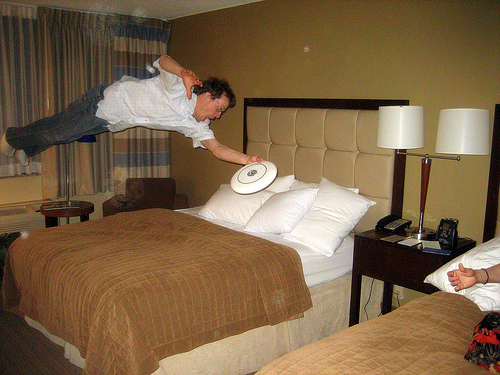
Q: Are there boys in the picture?
A: No, there are no boys.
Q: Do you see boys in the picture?
A: No, there are no boys.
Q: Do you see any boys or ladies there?
A: No, there are no boys or ladies.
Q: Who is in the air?
A: The man is in the air.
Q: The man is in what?
A: The man is in the air.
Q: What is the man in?
A: The man is in the air.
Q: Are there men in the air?
A: Yes, there is a man in the air.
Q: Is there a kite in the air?
A: No, there is a man in the air.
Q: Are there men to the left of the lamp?
A: Yes, there is a man to the left of the lamp.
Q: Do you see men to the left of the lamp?
A: Yes, there is a man to the left of the lamp.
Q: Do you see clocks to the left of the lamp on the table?
A: No, there is a man to the left of the lamp.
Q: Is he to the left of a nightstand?
A: No, the man is to the left of the lamp.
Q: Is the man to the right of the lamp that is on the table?
A: No, the man is to the left of the lamp.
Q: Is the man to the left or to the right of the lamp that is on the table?
A: The man is to the left of the lamp.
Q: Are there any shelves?
A: No, there are no shelves.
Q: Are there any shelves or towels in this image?
A: No, there are no shelves or towels.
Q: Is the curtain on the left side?
A: Yes, the curtain is on the left of the image.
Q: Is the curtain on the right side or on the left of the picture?
A: The curtain is on the left of the image.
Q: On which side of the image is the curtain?
A: The curtain is on the left of the image.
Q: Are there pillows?
A: Yes, there is a pillow.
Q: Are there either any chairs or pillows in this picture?
A: Yes, there is a pillow.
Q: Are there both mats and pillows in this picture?
A: No, there is a pillow but no mats.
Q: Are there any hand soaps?
A: No, there are no hand soaps.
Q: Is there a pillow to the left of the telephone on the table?
A: Yes, there is a pillow to the left of the phone.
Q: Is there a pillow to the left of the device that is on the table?
A: Yes, there is a pillow to the left of the phone.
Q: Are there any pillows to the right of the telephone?
A: No, the pillow is to the left of the telephone.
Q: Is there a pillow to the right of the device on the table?
A: No, the pillow is to the left of the telephone.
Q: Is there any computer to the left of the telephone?
A: No, there is a pillow to the left of the telephone.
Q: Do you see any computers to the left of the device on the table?
A: No, there is a pillow to the left of the telephone.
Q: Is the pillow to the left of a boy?
A: No, the pillow is to the left of a phone.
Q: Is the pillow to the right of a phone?
A: No, the pillow is to the left of a phone.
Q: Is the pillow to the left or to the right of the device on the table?
A: The pillow is to the left of the phone.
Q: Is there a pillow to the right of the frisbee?
A: Yes, there is a pillow to the right of the frisbee.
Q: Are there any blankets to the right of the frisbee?
A: No, there is a pillow to the right of the frisbee.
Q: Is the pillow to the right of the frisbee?
A: Yes, the pillow is to the right of the frisbee.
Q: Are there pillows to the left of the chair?
A: No, the pillow is to the right of the chair.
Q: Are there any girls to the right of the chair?
A: No, there is a pillow to the right of the chair.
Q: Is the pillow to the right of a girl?
A: No, the pillow is to the right of the chair.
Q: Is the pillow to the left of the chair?
A: No, the pillow is to the right of the chair.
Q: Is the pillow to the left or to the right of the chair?
A: The pillow is to the right of the chair.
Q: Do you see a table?
A: Yes, there is a table.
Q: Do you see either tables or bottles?
A: Yes, there is a table.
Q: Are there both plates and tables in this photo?
A: No, there is a table but no plates.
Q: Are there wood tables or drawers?
A: Yes, there is a wood table.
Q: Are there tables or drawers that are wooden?
A: Yes, the table is wooden.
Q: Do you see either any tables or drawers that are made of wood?
A: Yes, the table is made of wood.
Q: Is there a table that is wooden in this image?
A: Yes, there is a wood table.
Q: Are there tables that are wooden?
A: Yes, there is a table that is wooden.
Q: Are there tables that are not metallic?
A: Yes, there is a wooden table.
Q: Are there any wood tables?
A: Yes, there is a table that is made of wood.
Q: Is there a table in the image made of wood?
A: Yes, there is a table that is made of wood.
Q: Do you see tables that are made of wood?
A: Yes, there is a table that is made of wood.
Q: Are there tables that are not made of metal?
A: Yes, there is a table that is made of wood.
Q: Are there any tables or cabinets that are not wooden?
A: No, there is a table but it is wooden.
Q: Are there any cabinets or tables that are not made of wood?
A: No, there is a table but it is made of wood.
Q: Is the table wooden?
A: Yes, the table is wooden.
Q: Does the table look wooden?
A: Yes, the table is wooden.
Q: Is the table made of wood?
A: Yes, the table is made of wood.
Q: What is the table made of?
A: The table is made of wood.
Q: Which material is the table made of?
A: The table is made of wood.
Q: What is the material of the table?
A: The table is made of wood.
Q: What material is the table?
A: The table is made of wood.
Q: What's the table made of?
A: The table is made of wood.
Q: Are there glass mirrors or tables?
A: No, there is a table but it is wooden.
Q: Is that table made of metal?
A: No, the table is made of wood.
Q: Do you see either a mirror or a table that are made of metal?
A: No, there is a table but it is made of wood.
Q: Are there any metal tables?
A: No, there is a table but it is made of wood.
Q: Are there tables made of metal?
A: No, there is a table but it is made of wood.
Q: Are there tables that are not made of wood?
A: No, there is a table but it is made of wood.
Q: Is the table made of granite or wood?
A: The table is made of wood.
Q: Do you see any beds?
A: Yes, there is a bed.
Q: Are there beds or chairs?
A: Yes, there is a bed.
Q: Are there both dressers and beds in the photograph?
A: No, there is a bed but no dressers.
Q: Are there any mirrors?
A: No, there are no mirrors.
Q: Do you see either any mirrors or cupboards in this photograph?
A: No, there are no mirrors or cupboards.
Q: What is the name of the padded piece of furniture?
A: The piece of furniture is a bed.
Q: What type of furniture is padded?
A: The furniture is a bed.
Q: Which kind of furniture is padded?
A: The furniture is a bed.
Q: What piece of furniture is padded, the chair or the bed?
A: The bed is padded.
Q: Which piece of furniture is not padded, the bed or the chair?
A: The chair is not padded.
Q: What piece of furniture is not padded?
A: The piece of furniture is a chair.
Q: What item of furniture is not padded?
A: The piece of furniture is a chair.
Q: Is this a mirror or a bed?
A: This is a bed.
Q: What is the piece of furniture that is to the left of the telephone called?
A: The piece of furniture is a bed.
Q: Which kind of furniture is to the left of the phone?
A: The piece of furniture is a bed.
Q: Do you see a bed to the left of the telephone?
A: Yes, there is a bed to the left of the telephone.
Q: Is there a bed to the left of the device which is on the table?
A: Yes, there is a bed to the left of the telephone.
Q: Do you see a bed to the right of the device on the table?
A: No, the bed is to the left of the telephone.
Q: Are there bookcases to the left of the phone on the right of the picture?
A: No, there is a bed to the left of the telephone.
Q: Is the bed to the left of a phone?
A: Yes, the bed is to the left of a phone.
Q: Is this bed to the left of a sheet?
A: No, the bed is to the left of a phone.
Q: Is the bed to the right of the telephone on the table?
A: No, the bed is to the left of the telephone.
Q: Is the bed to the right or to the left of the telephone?
A: The bed is to the left of the telephone.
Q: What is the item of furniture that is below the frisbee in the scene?
A: The piece of furniture is a bed.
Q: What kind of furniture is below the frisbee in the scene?
A: The piece of furniture is a bed.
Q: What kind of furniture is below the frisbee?
A: The piece of furniture is a bed.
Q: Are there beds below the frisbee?
A: Yes, there is a bed below the frisbee.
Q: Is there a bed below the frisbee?
A: Yes, there is a bed below the frisbee.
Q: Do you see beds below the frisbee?
A: Yes, there is a bed below the frisbee.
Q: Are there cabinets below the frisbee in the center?
A: No, there is a bed below the frisbee.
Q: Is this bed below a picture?
A: No, the bed is below a frisbee.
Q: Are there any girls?
A: No, there are no girls.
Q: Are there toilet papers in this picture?
A: No, there are no toilet papers.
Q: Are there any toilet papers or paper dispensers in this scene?
A: No, there are no toilet papers or paper dispensers.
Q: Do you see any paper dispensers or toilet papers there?
A: No, there are no toilet papers or paper dispensers.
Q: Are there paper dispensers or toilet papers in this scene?
A: No, there are no toilet papers or paper dispensers.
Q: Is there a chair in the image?
A: Yes, there is a chair.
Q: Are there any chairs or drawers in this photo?
A: Yes, there is a chair.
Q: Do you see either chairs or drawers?
A: Yes, there is a chair.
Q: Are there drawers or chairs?
A: Yes, there is a chair.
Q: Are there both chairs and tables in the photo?
A: Yes, there are both a chair and a table.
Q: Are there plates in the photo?
A: No, there are no plates.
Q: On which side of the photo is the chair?
A: The chair is on the left of the image.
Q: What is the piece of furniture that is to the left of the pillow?
A: The piece of furniture is a chair.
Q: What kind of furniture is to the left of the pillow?
A: The piece of furniture is a chair.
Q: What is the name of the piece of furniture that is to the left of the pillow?
A: The piece of furniture is a chair.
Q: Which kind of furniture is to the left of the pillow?
A: The piece of furniture is a chair.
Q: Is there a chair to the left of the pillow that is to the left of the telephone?
A: Yes, there is a chair to the left of the pillow.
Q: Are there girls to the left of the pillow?
A: No, there is a chair to the left of the pillow.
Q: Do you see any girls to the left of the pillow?
A: No, there is a chair to the left of the pillow.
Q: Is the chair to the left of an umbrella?
A: No, the chair is to the left of the pillow.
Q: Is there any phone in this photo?
A: Yes, there is a phone.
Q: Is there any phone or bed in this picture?
A: Yes, there is a phone.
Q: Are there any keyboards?
A: No, there are no keyboards.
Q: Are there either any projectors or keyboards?
A: No, there are no keyboards or projectors.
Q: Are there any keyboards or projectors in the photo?
A: No, there are no keyboards or projectors.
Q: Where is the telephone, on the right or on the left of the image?
A: The telephone is on the right of the image.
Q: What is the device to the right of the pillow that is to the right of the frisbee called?
A: The device is a phone.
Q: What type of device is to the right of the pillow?
A: The device is a phone.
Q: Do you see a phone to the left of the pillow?
A: No, the phone is to the right of the pillow.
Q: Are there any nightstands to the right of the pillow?
A: No, there is a phone to the right of the pillow.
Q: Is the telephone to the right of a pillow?
A: Yes, the telephone is to the right of a pillow.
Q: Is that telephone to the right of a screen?
A: No, the telephone is to the right of a pillow.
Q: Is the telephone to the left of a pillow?
A: No, the telephone is to the right of a pillow.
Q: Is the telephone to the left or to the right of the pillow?
A: The telephone is to the right of the pillow.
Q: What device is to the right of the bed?
A: The device is a phone.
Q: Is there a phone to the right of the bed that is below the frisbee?
A: Yes, there is a phone to the right of the bed.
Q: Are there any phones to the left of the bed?
A: No, the phone is to the right of the bed.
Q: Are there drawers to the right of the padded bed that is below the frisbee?
A: No, there is a phone to the right of the bed.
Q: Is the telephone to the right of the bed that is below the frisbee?
A: Yes, the telephone is to the right of the bed.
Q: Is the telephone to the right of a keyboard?
A: No, the telephone is to the right of the bed.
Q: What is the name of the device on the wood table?
A: The device is a phone.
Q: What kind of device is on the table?
A: The device is a phone.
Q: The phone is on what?
A: The phone is on the table.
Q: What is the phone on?
A: The phone is on the table.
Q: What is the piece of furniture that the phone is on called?
A: The piece of furniture is a table.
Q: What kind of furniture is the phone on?
A: The phone is on the table.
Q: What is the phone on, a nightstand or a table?
A: The phone is on a table.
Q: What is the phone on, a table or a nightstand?
A: The phone is on a table.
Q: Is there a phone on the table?
A: Yes, there is a phone on the table.